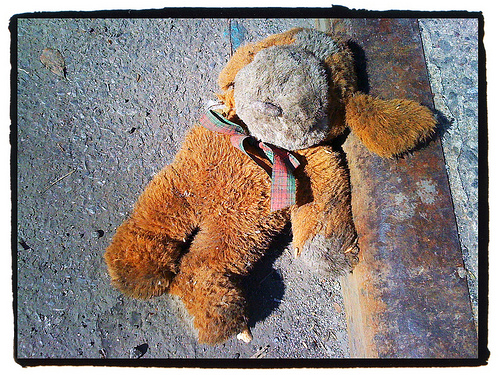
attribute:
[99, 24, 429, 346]
bear — grimy, dusty, dirty, brown, noseless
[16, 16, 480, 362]
ground — dirty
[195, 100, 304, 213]
ribbon — neat, green, red, plaid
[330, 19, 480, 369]
curb — rusty